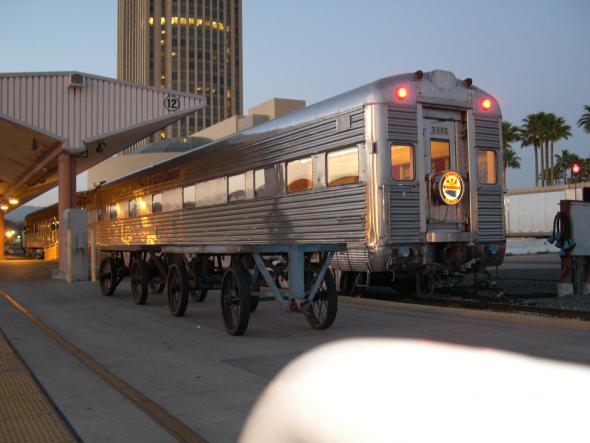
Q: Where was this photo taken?
A: At a train station.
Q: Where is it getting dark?
A: Train depot.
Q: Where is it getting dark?
A: At the train station.